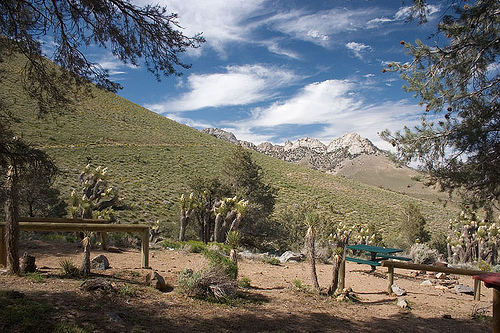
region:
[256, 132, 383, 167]
grey and white mountain top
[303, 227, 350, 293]
broken tree trunks in ground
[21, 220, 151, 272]
brown wooden hitching post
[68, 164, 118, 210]
green cactus in ground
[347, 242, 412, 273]
green metal picnic table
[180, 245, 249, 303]
green bush in ground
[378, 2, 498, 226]
tree with green leaves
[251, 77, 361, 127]
white cloud in sky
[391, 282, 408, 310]
grey rocks on ground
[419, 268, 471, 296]
rocks laying on ground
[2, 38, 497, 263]
hillside with green on it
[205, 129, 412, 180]
snow capped mountains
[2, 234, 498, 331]
dry desert soil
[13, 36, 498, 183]
blue sky with thin clouds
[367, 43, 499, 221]
branches of a conifer tree with cones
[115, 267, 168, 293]
an earthy toned rock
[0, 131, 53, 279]
a desert tree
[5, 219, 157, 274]
a smooth wooden railing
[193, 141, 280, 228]
a bushy fir tree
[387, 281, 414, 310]
a couple of light color rocks that look stacked on each other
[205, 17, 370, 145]
blue and white sky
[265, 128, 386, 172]
mountains in the background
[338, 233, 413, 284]
green bench on dirt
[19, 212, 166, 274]
wooden posts in the dirt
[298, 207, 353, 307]
cacti growing in the dirt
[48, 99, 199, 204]
grassy hill behind the benches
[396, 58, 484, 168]
green leaves on the trees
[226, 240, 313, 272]
rocks around the dirt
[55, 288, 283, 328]
shadows on the dirt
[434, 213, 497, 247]
white flowers on bushes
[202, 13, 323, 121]
wispy white clouds in the sky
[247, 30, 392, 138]
blue sky with picturesque clouds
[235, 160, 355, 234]
green hillside in the distance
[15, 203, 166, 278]
wooden man made fence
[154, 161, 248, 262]
scrubby desert trees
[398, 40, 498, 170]
evergreen branches on a tree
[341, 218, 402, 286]
green colored bench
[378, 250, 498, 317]
wooden bench for sitting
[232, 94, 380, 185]
mountain peaks in the distance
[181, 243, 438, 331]
row of shadows on the ground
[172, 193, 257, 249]
cacti in the desert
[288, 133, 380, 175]
mountain tops in the distance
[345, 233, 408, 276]
a picnic table with a view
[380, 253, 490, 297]
a part of a wooden fence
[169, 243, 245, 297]
a desert shrub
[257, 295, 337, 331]
sand and dirt on the desert floor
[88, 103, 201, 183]
sparce growth on a hillside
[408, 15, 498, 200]
branches of an evergreen tree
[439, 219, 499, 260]
a bunch of cacti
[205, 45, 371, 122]
white, whispy clouds in the sky